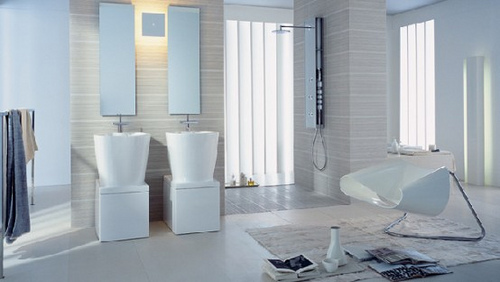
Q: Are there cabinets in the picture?
A: No, there are no cabinets.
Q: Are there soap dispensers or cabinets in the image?
A: No, there are no cabinets or soap dispensers.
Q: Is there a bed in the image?
A: No, there are no beds.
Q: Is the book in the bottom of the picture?
A: Yes, the book is in the bottom of the image.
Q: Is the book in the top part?
A: No, the book is in the bottom of the image.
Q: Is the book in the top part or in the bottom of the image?
A: The book is in the bottom of the image.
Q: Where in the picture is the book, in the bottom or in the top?
A: The book is in the bottom of the image.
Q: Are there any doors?
A: Yes, there is a door.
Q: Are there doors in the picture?
A: Yes, there is a door.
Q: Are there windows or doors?
A: Yes, there is a door.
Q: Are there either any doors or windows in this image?
A: Yes, there is a door.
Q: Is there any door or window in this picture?
A: Yes, there is a door.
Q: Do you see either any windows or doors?
A: Yes, there is a door.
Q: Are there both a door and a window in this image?
A: Yes, there are both a door and a window.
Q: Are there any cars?
A: No, there are no cars.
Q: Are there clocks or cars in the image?
A: No, there are no cars or clocks.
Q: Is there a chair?
A: Yes, there is a chair.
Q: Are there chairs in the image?
A: Yes, there is a chair.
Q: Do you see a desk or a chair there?
A: Yes, there is a chair.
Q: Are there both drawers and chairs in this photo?
A: No, there is a chair but no drawers.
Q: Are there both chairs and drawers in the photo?
A: No, there is a chair but no drawers.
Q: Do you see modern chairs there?
A: Yes, there is a modern chair.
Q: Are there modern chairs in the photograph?
A: Yes, there is a modern chair.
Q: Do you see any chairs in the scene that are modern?
A: Yes, there is a chair that is modern.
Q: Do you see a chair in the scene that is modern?
A: Yes, there is a chair that is modern.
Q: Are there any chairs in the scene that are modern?
A: Yes, there is a chair that is modern.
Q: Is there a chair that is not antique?
A: Yes, there is an modern chair.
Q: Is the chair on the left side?
A: No, the chair is on the right of the image.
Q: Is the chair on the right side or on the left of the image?
A: The chair is on the right of the image.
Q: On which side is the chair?
A: The chair is on the right of the image.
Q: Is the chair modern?
A: Yes, the chair is modern.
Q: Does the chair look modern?
A: Yes, the chair is modern.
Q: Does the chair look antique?
A: No, the chair is modern.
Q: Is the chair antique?
A: No, the chair is modern.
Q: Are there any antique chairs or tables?
A: No, there is a chair but it is modern.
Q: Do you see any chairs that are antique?
A: No, there is a chair but it is modern.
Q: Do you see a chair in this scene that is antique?
A: No, there is a chair but it is modern.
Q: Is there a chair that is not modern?
A: No, there is a chair but it is modern.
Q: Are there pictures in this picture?
A: No, there are no pictures.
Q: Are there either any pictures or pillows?
A: No, there are no pictures or pillows.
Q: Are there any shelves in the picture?
A: No, there are no shelves.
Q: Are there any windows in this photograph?
A: Yes, there is a window.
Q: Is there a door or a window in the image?
A: Yes, there is a window.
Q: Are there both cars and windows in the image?
A: No, there is a window but no cars.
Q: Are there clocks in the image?
A: No, there are no clocks.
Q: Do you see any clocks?
A: No, there are no clocks.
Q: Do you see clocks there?
A: No, there are no clocks.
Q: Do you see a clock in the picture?
A: No, there are no clocks.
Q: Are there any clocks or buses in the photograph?
A: No, there are no clocks or buses.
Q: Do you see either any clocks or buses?
A: No, there are no clocks or buses.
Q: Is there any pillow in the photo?
A: No, there are no pillows.